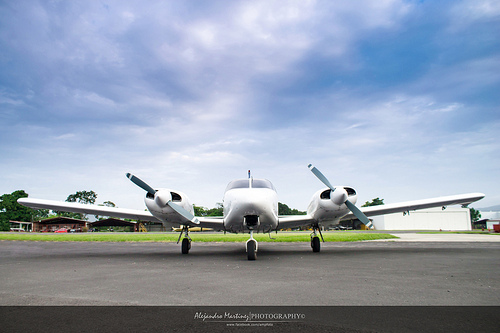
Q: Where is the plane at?
A: Parking lot.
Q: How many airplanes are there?
A: One.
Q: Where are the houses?
A: Across the field.